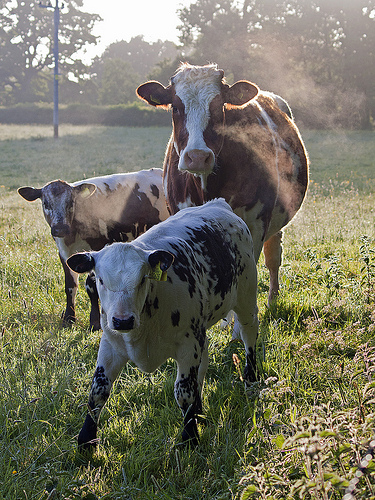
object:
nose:
[177, 151, 221, 174]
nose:
[52, 217, 69, 235]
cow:
[128, 60, 312, 317]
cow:
[13, 165, 177, 333]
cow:
[60, 198, 277, 460]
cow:
[133, 52, 310, 245]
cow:
[14, 163, 171, 336]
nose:
[102, 310, 136, 337]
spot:
[169, 308, 181, 328]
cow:
[65, 195, 263, 500]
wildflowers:
[318, 406, 348, 452]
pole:
[46, 1, 64, 140]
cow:
[16, 167, 170, 334]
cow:
[136, 63, 312, 314]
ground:
[252, 122, 278, 147]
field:
[1, 125, 373, 498]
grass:
[3, 122, 373, 498]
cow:
[134, 55, 315, 320]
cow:
[17, 160, 171, 331]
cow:
[58, 194, 277, 453]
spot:
[190, 217, 243, 303]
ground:
[246, 79, 274, 106]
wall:
[0, 104, 165, 127]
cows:
[133, 55, 312, 325]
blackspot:
[168, 310, 183, 327]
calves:
[62, 197, 257, 460]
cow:
[11, 164, 169, 341]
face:
[37, 179, 83, 243]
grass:
[289, 251, 357, 341]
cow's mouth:
[174, 161, 216, 177]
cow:
[64, 197, 259, 462]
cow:
[135, 60, 310, 302]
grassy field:
[1, 123, 373, 497]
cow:
[135, 59, 311, 309]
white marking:
[174, 62, 214, 149]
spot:
[191, 351, 199, 361]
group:
[15, 59, 312, 453]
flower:
[9, 468, 20, 475]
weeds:
[281, 286, 304, 346]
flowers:
[224, 351, 262, 387]